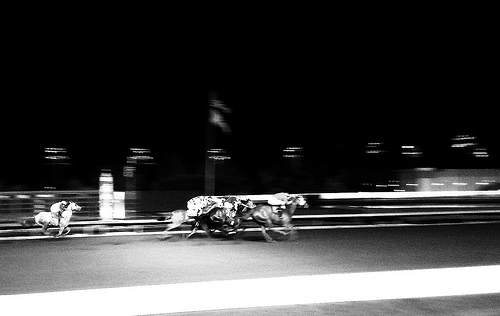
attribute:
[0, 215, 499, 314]
track — grey dirt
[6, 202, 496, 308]
track — dirt track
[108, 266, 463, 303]
rail — white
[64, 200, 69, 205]
hat — white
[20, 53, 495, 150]
sky — black, dark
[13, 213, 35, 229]
tail — black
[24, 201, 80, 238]
horse — race horse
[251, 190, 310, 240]
horse — race horse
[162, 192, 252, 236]
horse — race horse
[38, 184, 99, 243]
horse — light colored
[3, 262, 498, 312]
line — wide, white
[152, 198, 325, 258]
light — artificial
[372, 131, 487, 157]
lights — blurry, shining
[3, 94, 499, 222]
lights — blurred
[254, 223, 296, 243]
legs — white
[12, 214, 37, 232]
tail — long